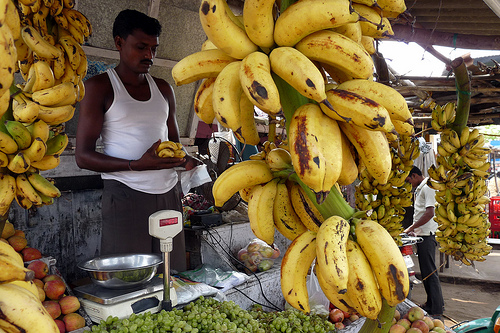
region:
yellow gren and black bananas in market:
[6, 10, 74, 115]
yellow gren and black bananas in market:
[2, 105, 64, 212]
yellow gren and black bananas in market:
[283, 224, 404, 312]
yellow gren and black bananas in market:
[197, 4, 384, 103]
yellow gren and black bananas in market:
[222, 108, 402, 215]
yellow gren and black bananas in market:
[428, 124, 492, 261]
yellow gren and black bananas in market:
[416, 79, 485, 125]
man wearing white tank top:
[106, 77, 168, 134]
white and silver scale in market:
[77, 205, 190, 304]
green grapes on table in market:
[128, 310, 254, 331]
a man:
[69, 6, 199, 276]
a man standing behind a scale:
[71, 1, 211, 331]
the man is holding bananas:
[70, 3, 193, 275]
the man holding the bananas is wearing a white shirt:
[70, 6, 210, 276]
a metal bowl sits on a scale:
[78, 202, 195, 326]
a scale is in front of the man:
[69, 211, 229, 322]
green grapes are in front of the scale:
[84, 282, 337, 330]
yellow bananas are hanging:
[3, 2, 498, 331]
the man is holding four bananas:
[65, 5, 225, 279]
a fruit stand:
[4, 5, 445, 331]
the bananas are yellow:
[5, 1, 496, 331]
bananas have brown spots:
[1, 1, 497, 311]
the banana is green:
[272, 65, 309, 112]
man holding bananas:
[72, 1, 210, 283]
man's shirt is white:
[83, 56, 200, 196]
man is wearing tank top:
[78, 51, 201, 204]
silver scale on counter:
[60, 240, 240, 317]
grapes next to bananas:
[93, 304, 330, 330]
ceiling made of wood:
[400, 0, 495, 62]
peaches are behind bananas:
[1, 224, 101, 328]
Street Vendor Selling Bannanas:
[73, 6, 209, 266]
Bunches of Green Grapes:
[90, 295, 337, 332]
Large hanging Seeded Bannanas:
[181, 0, 436, 315]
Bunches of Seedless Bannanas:
[434, 93, 497, 265]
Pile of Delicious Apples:
[387, 301, 450, 331]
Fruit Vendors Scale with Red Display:
[71, 203, 221, 320]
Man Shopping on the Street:
[404, 166, 460, 322]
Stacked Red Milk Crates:
[489, 192, 499, 244]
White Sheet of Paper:
[179, 160, 211, 197]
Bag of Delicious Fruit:
[233, 237, 285, 274]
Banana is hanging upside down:
[0, 1, 490, 321]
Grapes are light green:
[93, 293, 337, 332]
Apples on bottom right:
[386, 305, 448, 332]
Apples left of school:
[3, 220, 86, 332]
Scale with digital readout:
[73, 208, 181, 313]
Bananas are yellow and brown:
[1, 1, 492, 316]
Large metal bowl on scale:
[76, 256, 164, 286]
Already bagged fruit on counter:
[231, 236, 280, 273]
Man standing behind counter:
[71, 20, 188, 279]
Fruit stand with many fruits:
[1, 2, 488, 331]